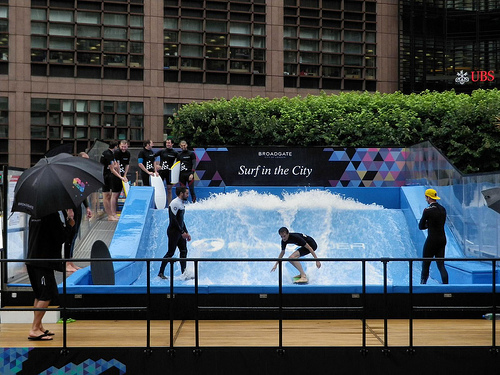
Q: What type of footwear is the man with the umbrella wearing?
A: Flip flops.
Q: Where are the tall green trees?
A: Behind the Surf in the City sign.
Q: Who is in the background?
A: A group of people.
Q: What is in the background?
A: A building.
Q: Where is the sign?
A: Behind the surfers.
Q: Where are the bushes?
A: Behind the sign.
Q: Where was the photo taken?
A: Outdoors in the city.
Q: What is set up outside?
A: A surf area.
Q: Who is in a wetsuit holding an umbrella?
A: A man.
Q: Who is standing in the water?
A: Two men.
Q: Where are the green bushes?
A: Behind the surf area.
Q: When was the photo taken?
A: During the daytime.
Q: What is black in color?
A: Umbrella.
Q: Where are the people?
A: Outside somewhere.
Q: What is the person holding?
A: Umbrella.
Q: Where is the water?
A: Under the surfer.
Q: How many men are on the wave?
A: 1.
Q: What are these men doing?
A: Surfing on an artificial wave.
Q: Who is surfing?
A: The man in the middle.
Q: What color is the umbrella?
A: Black.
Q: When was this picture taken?
A: During the day.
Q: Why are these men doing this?
A: Fun.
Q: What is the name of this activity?
A: Surf the city.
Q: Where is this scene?
A: In front of the USB building.